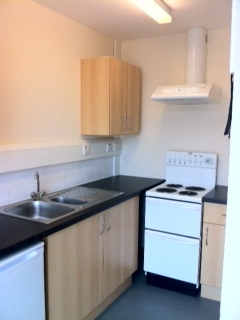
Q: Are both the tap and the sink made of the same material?
A: Yes, both the tap and the sink are made of metal.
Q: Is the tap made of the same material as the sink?
A: Yes, both the tap and the sink are made of metal.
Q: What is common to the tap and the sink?
A: The material, both the tap and the sink are metallic.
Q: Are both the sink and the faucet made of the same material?
A: Yes, both the sink and the faucet are made of metal.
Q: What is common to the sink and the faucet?
A: The material, both the sink and the faucet are metallic.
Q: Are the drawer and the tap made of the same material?
A: No, the drawer is made of wood and the tap is made of metal.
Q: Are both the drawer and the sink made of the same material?
A: No, the drawer is made of wood and the sink is made of metal.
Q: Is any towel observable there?
A: No, there are no towels.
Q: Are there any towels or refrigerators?
A: No, there are no towels or refrigerators.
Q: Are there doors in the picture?
A: Yes, there is a door.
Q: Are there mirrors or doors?
A: Yes, there is a door.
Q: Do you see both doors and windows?
A: No, there is a door but no windows.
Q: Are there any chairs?
A: No, there are no chairs.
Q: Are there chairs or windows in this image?
A: No, there are no chairs or windows.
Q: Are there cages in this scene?
A: No, there are no cages.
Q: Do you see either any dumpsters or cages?
A: No, there are no cages or dumpsters.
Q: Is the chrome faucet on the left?
A: Yes, the faucet is on the left of the image.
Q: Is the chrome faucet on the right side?
A: No, the faucet is on the left of the image.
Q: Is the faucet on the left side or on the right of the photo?
A: The faucet is on the left of the image.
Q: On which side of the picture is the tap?
A: The tap is on the left of the image.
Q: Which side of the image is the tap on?
A: The tap is on the left of the image.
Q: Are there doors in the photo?
A: Yes, there is a door.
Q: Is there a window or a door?
A: Yes, there is a door.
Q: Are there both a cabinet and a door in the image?
A: Yes, there are both a door and a cabinet.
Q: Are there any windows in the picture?
A: No, there are no windows.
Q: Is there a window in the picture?
A: No, there are no windows.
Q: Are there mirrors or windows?
A: No, there are no windows or mirrors.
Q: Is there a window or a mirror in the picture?
A: No, there are no windows or mirrors.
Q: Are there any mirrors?
A: No, there are no mirrors.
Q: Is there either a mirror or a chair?
A: No, there are no mirrors or chairs.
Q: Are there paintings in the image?
A: No, there are no paintings.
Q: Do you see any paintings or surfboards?
A: No, there are no paintings or surfboards.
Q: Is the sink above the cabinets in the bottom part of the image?
A: Yes, the sink is above the cabinets.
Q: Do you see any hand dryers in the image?
A: No, there are no hand dryers.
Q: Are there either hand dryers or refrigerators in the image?
A: No, there are no hand dryers or refrigerators.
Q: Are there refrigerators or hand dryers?
A: No, there are no hand dryers or refrigerators.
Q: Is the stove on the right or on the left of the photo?
A: The stove is on the right of the image.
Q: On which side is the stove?
A: The stove is on the right of the image.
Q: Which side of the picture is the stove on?
A: The stove is on the right of the image.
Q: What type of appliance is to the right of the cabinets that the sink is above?
A: The appliance is a stove.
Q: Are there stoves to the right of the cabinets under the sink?
A: Yes, there is a stove to the right of the cabinets.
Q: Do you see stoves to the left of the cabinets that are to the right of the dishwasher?
A: No, the stove is to the right of the cabinets.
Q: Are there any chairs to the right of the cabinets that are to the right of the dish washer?
A: No, there is a stove to the right of the cabinets.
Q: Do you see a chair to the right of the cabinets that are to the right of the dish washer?
A: No, there is a stove to the right of the cabinets.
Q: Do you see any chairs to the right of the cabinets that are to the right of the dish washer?
A: No, there is a stove to the right of the cabinets.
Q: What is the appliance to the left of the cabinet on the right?
A: The appliance is a stove.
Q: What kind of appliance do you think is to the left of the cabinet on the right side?
A: The appliance is a stove.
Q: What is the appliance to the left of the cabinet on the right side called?
A: The appliance is a stove.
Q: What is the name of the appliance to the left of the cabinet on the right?
A: The appliance is a stove.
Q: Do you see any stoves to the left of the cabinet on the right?
A: Yes, there is a stove to the left of the cabinet.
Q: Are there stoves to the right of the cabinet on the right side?
A: No, the stove is to the left of the cabinet.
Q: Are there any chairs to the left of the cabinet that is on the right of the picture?
A: No, there is a stove to the left of the cabinet.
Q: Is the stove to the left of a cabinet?
A: Yes, the stove is to the left of a cabinet.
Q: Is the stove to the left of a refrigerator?
A: No, the stove is to the left of a cabinet.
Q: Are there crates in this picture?
A: No, there are no crates.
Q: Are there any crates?
A: No, there are no crates.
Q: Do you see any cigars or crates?
A: No, there are no crates or cigars.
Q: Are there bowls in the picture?
A: No, there are no bowls.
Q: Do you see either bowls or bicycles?
A: No, there are no bowls or bicycles.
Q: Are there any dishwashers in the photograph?
A: Yes, there is a dishwasher.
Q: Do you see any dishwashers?
A: Yes, there is a dishwasher.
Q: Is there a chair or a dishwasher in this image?
A: Yes, there is a dishwasher.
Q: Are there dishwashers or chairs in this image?
A: Yes, there is a dishwasher.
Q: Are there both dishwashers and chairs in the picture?
A: No, there is a dishwasher but no chairs.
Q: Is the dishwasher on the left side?
A: Yes, the dishwasher is on the left of the image.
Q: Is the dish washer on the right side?
A: No, the dish washer is on the left of the image.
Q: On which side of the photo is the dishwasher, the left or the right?
A: The dishwasher is on the left of the image.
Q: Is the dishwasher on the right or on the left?
A: The dishwasher is on the left of the image.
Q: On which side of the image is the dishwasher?
A: The dishwasher is on the left of the image.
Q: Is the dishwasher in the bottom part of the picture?
A: Yes, the dishwasher is in the bottom of the image.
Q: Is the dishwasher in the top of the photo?
A: No, the dishwasher is in the bottom of the image.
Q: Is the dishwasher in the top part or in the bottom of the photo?
A: The dishwasher is in the bottom of the image.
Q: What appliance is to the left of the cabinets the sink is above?
A: The appliance is a dishwasher.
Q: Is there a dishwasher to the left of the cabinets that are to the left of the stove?
A: Yes, there is a dishwasher to the left of the cabinets.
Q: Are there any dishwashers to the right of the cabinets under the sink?
A: No, the dishwasher is to the left of the cabinets.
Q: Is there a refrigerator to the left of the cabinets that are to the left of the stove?
A: No, there is a dishwasher to the left of the cabinets.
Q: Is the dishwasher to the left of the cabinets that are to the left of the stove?
A: Yes, the dishwasher is to the left of the cabinets.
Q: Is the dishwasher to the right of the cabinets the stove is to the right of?
A: No, the dishwasher is to the left of the cabinets.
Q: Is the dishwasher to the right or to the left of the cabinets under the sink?
A: The dishwasher is to the left of the cabinets.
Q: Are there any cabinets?
A: Yes, there is a cabinet.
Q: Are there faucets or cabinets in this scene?
A: Yes, there is a cabinet.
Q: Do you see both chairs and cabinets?
A: No, there is a cabinet but no chairs.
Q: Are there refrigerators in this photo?
A: No, there are no refrigerators.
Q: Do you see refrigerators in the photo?
A: No, there are no refrigerators.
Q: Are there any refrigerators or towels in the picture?
A: No, there are no refrigerators or towels.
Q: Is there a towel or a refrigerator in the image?
A: No, there are no refrigerators or towels.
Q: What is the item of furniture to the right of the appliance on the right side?
A: The piece of furniture is a cabinet.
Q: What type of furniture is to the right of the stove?
A: The piece of furniture is a cabinet.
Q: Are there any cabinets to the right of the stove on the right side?
A: Yes, there is a cabinet to the right of the stove.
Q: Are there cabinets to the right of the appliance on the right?
A: Yes, there is a cabinet to the right of the stove.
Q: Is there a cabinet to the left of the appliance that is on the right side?
A: No, the cabinet is to the right of the stove.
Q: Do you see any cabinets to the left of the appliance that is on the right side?
A: No, the cabinet is to the right of the stove.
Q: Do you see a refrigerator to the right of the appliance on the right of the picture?
A: No, there is a cabinet to the right of the stove.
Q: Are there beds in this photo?
A: No, there are no beds.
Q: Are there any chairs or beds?
A: No, there are no beds or chairs.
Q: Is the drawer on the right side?
A: Yes, the drawer is on the right of the image.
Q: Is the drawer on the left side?
A: No, the drawer is on the right of the image.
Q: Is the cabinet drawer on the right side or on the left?
A: The drawer is on the right of the image.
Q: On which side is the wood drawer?
A: The drawer is on the right of the image.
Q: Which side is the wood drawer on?
A: The drawer is on the right of the image.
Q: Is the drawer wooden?
A: Yes, the drawer is wooden.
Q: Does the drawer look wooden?
A: Yes, the drawer is wooden.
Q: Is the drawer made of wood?
A: Yes, the drawer is made of wood.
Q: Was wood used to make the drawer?
A: Yes, the drawer is made of wood.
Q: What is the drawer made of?
A: The drawer is made of wood.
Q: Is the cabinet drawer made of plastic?
A: No, the drawer is made of wood.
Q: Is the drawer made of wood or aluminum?
A: The drawer is made of wood.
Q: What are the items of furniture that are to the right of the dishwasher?
A: The pieces of furniture are cabinets.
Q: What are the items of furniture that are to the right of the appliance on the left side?
A: The pieces of furniture are cabinets.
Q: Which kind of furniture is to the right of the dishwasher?
A: The pieces of furniture are cabinets.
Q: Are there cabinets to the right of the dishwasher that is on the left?
A: Yes, there are cabinets to the right of the dish washer.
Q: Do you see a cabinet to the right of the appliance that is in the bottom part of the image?
A: Yes, there are cabinets to the right of the dish washer.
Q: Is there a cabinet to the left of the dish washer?
A: No, the cabinets are to the right of the dish washer.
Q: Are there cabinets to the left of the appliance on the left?
A: No, the cabinets are to the right of the dish washer.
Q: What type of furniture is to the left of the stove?
A: The pieces of furniture are cabinets.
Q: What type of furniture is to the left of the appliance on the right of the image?
A: The pieces of furniture are cabinets.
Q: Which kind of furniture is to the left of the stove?
A: The pieces of furniture are cabinets.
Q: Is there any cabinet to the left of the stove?
A: Yes, there are cabinets to the left of the stove.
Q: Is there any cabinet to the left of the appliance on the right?
A: Yes, there are cabinets to the left of the stove.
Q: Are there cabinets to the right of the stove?
A: No, the cabinets are to the left of the stove.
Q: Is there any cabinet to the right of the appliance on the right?
A: No, the cabinets are to the left of the stove.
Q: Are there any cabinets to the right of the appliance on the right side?
A: No, the cabinets are to the left of the stove.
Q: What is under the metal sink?
A: The cabinets are under the sink.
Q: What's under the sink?
A: The cabinets are under the sink.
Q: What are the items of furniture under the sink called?
A: The pieces of furniture are cabinets.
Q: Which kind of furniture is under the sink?
A: The pieces of furniture are cabinets.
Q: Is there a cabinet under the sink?
A: Yes, there are cabinets under the sink.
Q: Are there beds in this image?
A: No, there are no beds.